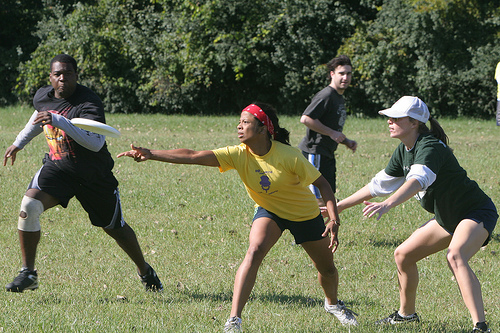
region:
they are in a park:
[3, 41, 495, 330]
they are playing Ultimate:
[19, 35, 481, 330]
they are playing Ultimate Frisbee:
[5, 30, 494, 332]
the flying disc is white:
[50, 105, 135, 157]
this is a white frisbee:
[60, 103, 144, 172]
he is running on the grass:
[3, 39, 181, 325]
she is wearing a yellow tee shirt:
[181, 71, 363, 285]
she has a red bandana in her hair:
[232, 92, 302, 172]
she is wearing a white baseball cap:
[370, 79, 467, 148]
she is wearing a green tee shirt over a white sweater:
[373, 80, 498, 250]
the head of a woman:
[220, 90, 295, 162]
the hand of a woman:
[106, 133, 166, 198]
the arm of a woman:
[108, 135, 249, 194]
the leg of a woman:
[200, 205, 306, 325]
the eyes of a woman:
[218, 98, 270, 160]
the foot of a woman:
[313, 286, 364, 327]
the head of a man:
[43, 11, 113, 118]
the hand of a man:
[29, 85, 73, 142]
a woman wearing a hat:
[366, 69, 462, 163]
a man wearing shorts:
[9, 120, 131, 255]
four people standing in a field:
[9, 43, 494, 327]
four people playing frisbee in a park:
[14, 51, 489, 326]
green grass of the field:
[147, 185, 225, 255]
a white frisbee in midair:
[68, 111, 124, 148]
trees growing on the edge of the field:
[106, 10, 301, 100]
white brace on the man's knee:
[12, 192, 52, 247]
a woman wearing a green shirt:
[350, 88, 498, 325]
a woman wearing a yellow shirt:
[206, 103, 359, 323]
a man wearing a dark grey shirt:
[299, 58, 366, 241]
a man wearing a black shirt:
[0, 49, 167, 290]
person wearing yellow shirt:
[115, 92, 364, 331]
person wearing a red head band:
[106, 98, 379, 330]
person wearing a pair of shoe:
[111, 91, 373, 331]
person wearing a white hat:
[314, 89, 499, 331]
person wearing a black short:
[5, 53, 177, 293]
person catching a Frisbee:
[61, 92, 361, 332]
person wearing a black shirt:
[276, 46, 364, 232]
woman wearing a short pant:
[113, 89, 371, 327]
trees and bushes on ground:
[15, 3, 493, 123]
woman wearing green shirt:
[313, 89, 495, 331]